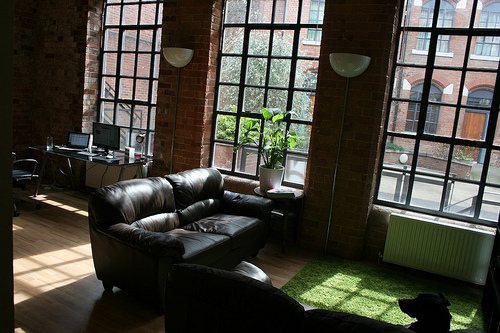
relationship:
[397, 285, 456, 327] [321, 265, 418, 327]
dog on carpet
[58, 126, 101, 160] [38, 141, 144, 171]
laptop on desk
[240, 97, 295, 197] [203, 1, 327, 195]
plant by window